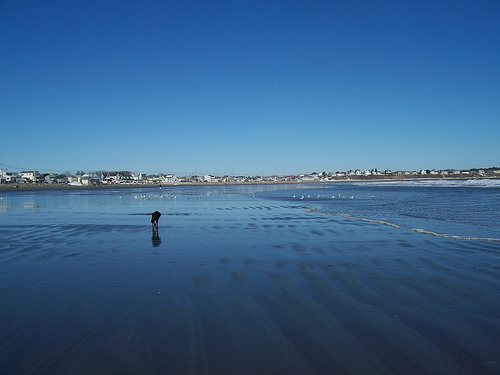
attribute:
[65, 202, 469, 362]
lake — frozen, icy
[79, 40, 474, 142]
sky — blue, cloudless, clear, beautiful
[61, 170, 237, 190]
buildings — white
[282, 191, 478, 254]
water — icy, shallow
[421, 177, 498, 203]
wave — white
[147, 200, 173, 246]
person — bending, standing, picking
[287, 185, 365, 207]
birds — swimming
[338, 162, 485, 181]
houses — long, around, distance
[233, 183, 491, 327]
ocean — blue, dark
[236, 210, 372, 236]
shadow — person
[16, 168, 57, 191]
house — reservior, around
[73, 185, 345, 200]
shoreline — blue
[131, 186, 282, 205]
seagulls — flocked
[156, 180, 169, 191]
person — walking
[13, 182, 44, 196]
dog — black